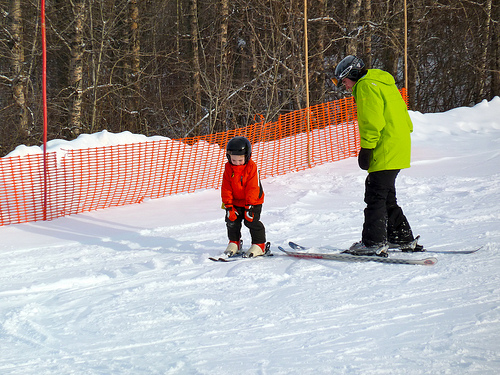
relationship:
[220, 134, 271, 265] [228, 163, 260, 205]
child has sweater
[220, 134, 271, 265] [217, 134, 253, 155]
child has helmet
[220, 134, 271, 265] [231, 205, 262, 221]
child has glove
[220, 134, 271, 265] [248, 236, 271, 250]
child has boot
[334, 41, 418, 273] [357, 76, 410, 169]
adult has jacket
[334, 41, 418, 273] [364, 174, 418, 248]
adult has pants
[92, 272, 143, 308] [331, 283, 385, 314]
snow on hill